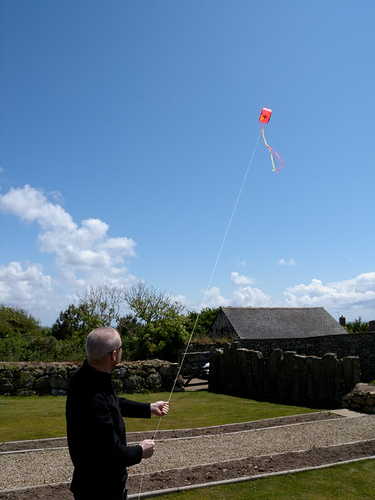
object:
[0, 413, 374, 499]
ground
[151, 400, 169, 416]
hand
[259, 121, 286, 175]
strings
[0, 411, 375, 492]
pathway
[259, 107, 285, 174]
kite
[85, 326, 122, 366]
hair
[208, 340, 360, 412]
wall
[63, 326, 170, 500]
man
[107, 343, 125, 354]
sunglasses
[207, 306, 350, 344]
roof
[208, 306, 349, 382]
building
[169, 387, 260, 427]
grass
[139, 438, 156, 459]
hand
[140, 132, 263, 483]
kite string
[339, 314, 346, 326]
chimney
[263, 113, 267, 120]
cross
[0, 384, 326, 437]
surface